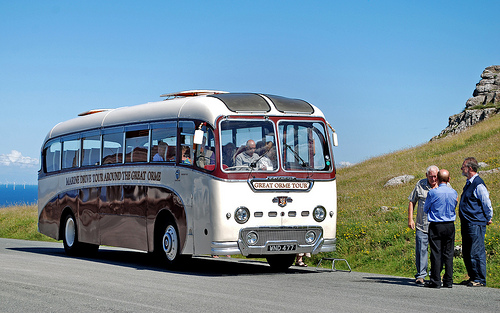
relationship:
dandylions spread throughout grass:
[362, 247, 369, 252] [340, 214, 407, 273]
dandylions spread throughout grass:
[392, 232, 400, 238] [340, 214, 407, 273]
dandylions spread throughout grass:
[404, 225, 411, 232] [340, 214, 407, 273]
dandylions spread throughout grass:
[359, 228, 366, 235] [340, 214, 407, 273]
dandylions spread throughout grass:
[343, 231, 350, 238] [340, 214, 407, 273]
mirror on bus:
[189, 123, 205, 154] [33, 89, 341, 265]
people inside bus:
[161, 137, 278, 174] [37, 89, 339, 270]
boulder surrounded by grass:
[380, 170, 417, 190] [3, 108, 498, 288]